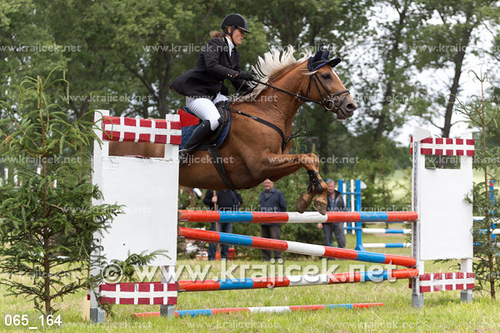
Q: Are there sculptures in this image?
A: No, there are no sculptures.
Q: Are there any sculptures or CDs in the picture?
A: No, there are no sculptures or cds.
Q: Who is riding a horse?
A: The jockey is riding a horse.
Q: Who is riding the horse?
A: The jockey is riding a horse.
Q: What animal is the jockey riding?
A: The jockey is riding a horse.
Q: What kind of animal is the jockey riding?
A: The jockey is riding a horse.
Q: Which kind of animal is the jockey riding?
A: The jockey is riding a horse.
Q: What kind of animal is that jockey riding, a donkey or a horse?
A: The jockey is riding a horse.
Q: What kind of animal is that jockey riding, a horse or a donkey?
A: The jockey is riding a horse.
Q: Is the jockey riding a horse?
A: Yes, the jockey is riding a horse.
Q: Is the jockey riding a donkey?
A: No, the jockey is riding a horse.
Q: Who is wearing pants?
A: The jockey is wearing pants.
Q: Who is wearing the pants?
A: The jockey is wearing pants.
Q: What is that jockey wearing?
A: The jockey is wearing trousers.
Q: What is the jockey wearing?
A: The jockey is wearing trousers.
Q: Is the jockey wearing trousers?
A: Yes, the jockey is wearing trousers.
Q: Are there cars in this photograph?
A: No, there are no cars.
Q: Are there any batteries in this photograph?
A: No, there are no batteries.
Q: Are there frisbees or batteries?
A: No, there are no batteries or frisbees.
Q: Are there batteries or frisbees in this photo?
A: No, there are no batteries or frisbees.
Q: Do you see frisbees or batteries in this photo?
A: No, there are no batteries or frisbees.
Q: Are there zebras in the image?
A: No, there are no zebras.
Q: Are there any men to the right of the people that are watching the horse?
A: Yes, there is a man to the right of the people.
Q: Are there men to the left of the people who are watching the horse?
A: No, the man is to the right of the people.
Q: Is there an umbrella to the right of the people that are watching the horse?
A: No, there is a man to the right of the people.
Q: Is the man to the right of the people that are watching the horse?
A: Yes, the man is to the right of the people.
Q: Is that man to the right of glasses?
A: No, the man is to the right of the people.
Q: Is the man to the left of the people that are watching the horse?
A: No, the man is to the right of the people.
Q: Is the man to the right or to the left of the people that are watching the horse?
A: The man is to the right of the people.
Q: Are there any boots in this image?
A: Yes, there are boots.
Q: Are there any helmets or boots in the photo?
A: Yes, there are boots.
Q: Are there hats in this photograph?
A: Yes, there is a hat.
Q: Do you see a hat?
A: Yes, there is a hat.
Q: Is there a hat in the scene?
A: Yes, there is a hat.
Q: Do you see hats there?
A: Yes, there is a hat.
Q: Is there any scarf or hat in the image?
A: Yes, there is a hat.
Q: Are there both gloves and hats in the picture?
A: Yes, there are both a hat and gloves.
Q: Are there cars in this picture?
A: No, there are no cars.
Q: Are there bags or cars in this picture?
A: No, there are no cars or bags.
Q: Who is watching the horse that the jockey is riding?
A: The people are watching the horse.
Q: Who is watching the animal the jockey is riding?
A: The people are watching the horse.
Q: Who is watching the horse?
A: The people are watching the horse.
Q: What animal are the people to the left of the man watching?
A: The people are watching the horse.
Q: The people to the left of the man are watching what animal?
A: The people are watching the horse.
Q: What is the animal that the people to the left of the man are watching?
A: The animal is a horse.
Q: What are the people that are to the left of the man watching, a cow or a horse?
A: The people are watching a horse.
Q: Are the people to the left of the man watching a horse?
A: Yes, the people are watching a horse.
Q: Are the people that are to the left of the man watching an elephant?
A: No, the people are watching a horse.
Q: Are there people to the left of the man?
A: Yes, there are people to the left of the man.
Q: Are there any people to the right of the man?
A: No, the people are to the left of the man.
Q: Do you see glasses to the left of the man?
A: No, there are people to the left of the man.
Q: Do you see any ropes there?
A: No, there are no ropes.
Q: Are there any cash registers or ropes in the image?
A: No, there are no ropes or cash registers.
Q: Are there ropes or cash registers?
A: No, there are no ropes or cash registers.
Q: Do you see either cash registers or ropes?
A: No, there are no ropes or cash registers.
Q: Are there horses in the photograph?
A: Yes, there is a horse.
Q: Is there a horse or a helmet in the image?
A: Yes, there is a horse.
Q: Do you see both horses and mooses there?
A: No, there is a horse but no mooses.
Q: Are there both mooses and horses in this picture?
A: No, there is a horse but no mooses.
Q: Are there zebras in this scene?
A: No, there are no zebras.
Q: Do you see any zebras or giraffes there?
A: No, there are no zebras or giraffes.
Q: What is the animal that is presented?
A: The animal is a horse.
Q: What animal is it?
A: The animal is a horse.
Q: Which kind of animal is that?
A: That is a horse.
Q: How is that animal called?
A: That is a horse.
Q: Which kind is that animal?
A: That is a horse.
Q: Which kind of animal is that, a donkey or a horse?
A: That is a horse.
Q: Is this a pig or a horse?
A: This is a horse.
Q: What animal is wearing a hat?
A: The horse is wearing a hat.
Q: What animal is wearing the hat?
A: The horse is wearing a hat.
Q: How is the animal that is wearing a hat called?
A: The animal is a horse.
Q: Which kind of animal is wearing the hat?
A: The animal is a horse.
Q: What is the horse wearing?
A: The horse is wearing a hat.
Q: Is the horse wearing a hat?
A: Yes, the horse is wearing a hat.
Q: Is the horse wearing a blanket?
A: No, the horse is wearing a hat.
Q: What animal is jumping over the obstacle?
A: The horse is jumping over the obstacle.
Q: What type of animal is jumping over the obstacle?
A: The animal is a horse.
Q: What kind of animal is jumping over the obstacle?
A: The animal is a horse.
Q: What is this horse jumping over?
A: The horse is jumping over the obstacle.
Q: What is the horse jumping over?
A: The horse is jumping over the obstacle.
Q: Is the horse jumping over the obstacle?
A: Yes, the horse is jumping over the obstacle.